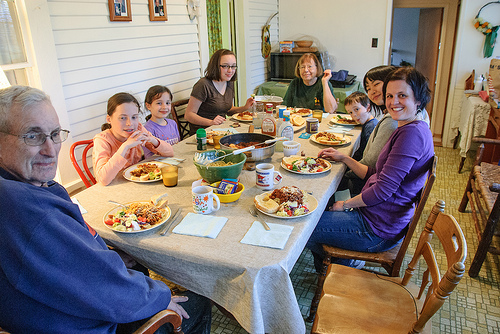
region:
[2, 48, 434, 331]
people sitting at a long table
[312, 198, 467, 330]
a wooden chair in front of a table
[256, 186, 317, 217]
a plate full of food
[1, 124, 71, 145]
a man wearing glasses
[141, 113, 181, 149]
a girl wearing a purple shirt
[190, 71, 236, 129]
a young woman wearing a brown shirt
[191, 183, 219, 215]
a colorful cup on a table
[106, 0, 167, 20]
two wooden framed pictures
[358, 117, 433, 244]
a woman wearing a purple shirt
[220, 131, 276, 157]
a silver bowl on a table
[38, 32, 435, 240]
people sitting at table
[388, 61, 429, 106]
woman has brown hair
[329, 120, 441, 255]
woman has purple shirt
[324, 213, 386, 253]
woman has blue jeans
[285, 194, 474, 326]
brown chair is empty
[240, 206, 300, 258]
white napkins on table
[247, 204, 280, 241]
steel utensil on napkin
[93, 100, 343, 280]
tablecloth is light grey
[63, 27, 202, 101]
white wall behind people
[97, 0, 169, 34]
brown picture frames on wall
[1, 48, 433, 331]
several people sitting round a table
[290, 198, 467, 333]
an empty wooden chair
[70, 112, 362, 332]
a table set with a white tablecloth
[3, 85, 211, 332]
older gentleman sitting in a chair with arms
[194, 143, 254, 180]
large green bowl with a utensil in it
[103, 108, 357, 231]
plates laden with food on table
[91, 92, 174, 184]
girl leaning forward with her elbows on table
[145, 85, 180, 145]
little girl with brown hair is smiling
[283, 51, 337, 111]
older woman with her hand up near her face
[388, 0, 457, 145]
an open door in the background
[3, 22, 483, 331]
a family is having dinner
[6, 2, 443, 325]
people eating around a table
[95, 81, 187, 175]
two little smiling girls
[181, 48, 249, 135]
woman wears glasses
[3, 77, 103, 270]
an old man has gray hair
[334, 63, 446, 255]
woman wears a purple top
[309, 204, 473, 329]
a chair of wood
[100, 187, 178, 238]
a dish full of food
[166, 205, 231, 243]
a napkin over a table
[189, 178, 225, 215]
a cup over a table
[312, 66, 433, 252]
A woman is sitting down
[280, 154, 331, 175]
Food is on the plate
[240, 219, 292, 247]
The napkin is white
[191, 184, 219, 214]
A mug on the table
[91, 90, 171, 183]
Girl looking at camera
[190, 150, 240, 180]
The bowl is green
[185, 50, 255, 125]
A woman is smiling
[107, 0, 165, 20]
Pictures on the wall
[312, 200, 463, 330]
Chair made of wood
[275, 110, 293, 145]
Bottle of salad dressing